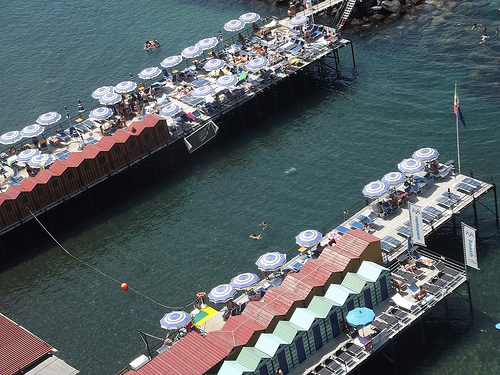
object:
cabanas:
[356, 260, 393, 305]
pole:
[454, 83, 461, 174]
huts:
[142, 114, 171, 147]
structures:
[216, 260, 392, 374]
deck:
[198, 162, 494, 374]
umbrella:
[247, 58, 267, 69]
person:
[156, 42, 160, 47]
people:
[250, 233, 263, 239]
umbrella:
[381, 172, 406, 185]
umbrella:
[207, 284, 237, 304]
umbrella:
[229, 272, 259, 288]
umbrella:
[90, 107, 112, 119]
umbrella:
[346, 308, 375, 326]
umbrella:
[362, 181, 389, 199]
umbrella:
[193, 85, 213, 96]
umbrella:
[397, 158, 424, 173]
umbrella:
[412, 147, 440, 162]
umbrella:
[295, 230, 323, 248]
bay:
[357, 0, 500, 82]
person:
[259, 221, 268, 230]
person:
[471, 24, 478, 31]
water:
[2, 5, 496, 374]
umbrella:
[160, 55, 182, 68]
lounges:
[455, 178, 481, 196]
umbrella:
[255, 251, 287, 271]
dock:
[0, 12, 355, 236]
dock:
[114, 146, 498, 374]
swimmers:
[226, 217, 281, 249]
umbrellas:
[239, 12, 260, 23]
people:
[481, 34, 489, 41]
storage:
[318, 246, 361, 278]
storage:
[299, 259, 344, 295]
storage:
[280, 272, 324, 308]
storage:
[262, 287, 306, 321]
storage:
[241, 301, 286, 333]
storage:
[335, 229, 383, 265]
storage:
[222, 315, 266, 347]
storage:
[340, 272, 378, 310]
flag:
[454, 83, 467, 127]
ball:
[121, 282, 128, 289]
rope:
[29, 210, 200, 309]